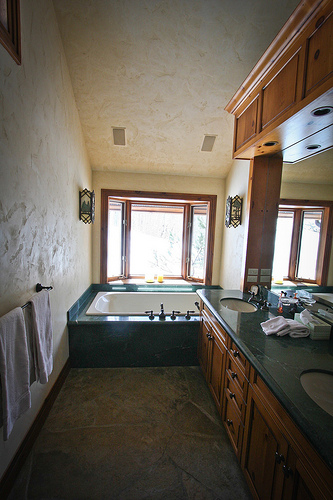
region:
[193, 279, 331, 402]
a green bathroom counter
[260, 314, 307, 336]
two folded towels on the counter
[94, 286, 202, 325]
a large white bath tub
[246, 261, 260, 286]
white electrical outlets on the wall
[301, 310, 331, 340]
a box of tissue on a counter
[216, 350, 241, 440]
wood knobs on draws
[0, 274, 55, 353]
two towels hanging on a rod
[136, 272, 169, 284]
two candles in a window sill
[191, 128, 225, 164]
heating and air vent in the cieling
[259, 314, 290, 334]
a towel on a bathroom counter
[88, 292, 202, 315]
A white bathtub.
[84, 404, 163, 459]
part of the floor.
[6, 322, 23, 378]
Part of a white towel.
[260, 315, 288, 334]
A white washcloth.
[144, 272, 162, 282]
Two candles on the counter.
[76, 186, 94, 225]
A light on the wall.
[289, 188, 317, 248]
Part of the mirror.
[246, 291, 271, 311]
The sink faucet and handles.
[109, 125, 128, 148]
A vent on the ceiling.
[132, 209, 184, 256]
Part of the window.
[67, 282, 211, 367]
jetted tub surrounded bu marble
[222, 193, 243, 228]
sconce on wall above tub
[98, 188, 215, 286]
bay window beside tub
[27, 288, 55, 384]
white towel hanging on towel rack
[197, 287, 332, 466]
bathroom counter with double sinks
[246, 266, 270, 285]
electrical outlets above counter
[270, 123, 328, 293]
mirror reflecting tub and window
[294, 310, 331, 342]
box of facial tissues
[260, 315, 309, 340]
folded hand towel and washcloth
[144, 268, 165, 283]
candles on window sill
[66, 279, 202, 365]
this bathtub is made of aqua marble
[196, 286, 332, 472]
the aqua marble countertop matches the bathtub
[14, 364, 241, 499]
the floor is a faux marble to match the tub and counter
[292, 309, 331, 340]
tissue box on the bathroom counter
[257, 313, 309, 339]
hand towels laid out on the counter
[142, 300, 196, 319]
the bathroom has brass fixtures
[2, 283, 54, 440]
bath towels are hanging on the wall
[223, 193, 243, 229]
pretty wall sconces for the lights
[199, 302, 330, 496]
the cabinetry is dark brown wood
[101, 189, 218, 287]
a picture window next to the bathtub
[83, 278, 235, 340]
a white and green bath tub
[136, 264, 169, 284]
candles on the ledge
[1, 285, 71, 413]
two white towels on rack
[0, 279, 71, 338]
a black towel rack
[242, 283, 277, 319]
black plumbing fixtures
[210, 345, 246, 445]
four drawers in the center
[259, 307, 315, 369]
two white towels on counter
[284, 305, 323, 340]
a box of tissues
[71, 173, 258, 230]
two candle holders on the walls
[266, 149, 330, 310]
a mirror above the counter